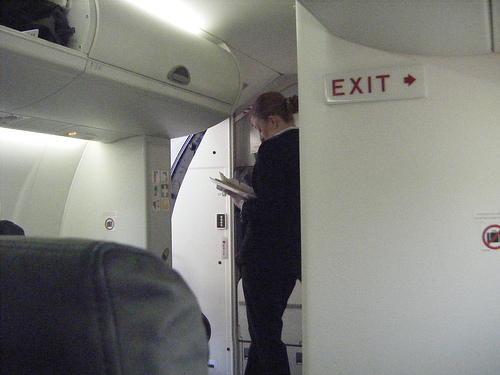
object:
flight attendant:
[213, 74, 307, 375]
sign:
[311, 65, 433, 106]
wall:
[304, 1, 500, 375]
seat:
[0, 234, 218, 374]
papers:
[207, 170, 261, 205]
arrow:
[402, 71, 420, 89]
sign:
[475, 214, 500, 254]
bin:
[0, 2, 93, 98]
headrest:
[1, 228, 218, 375]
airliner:
[0, 0, 491, 375]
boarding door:
[168, 110, 250, 373]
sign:
[98, 217, 123, 233]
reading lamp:
[58, 123, 83, 143]